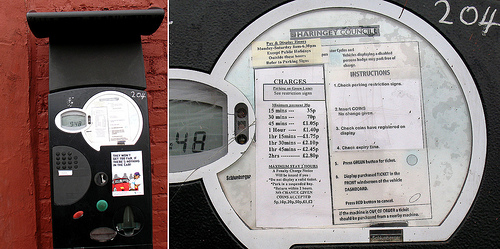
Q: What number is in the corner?
A: 204.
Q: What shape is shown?
A: Circle.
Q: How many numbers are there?
A: Five.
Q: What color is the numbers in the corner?
A: White.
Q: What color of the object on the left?
A: Black and white.